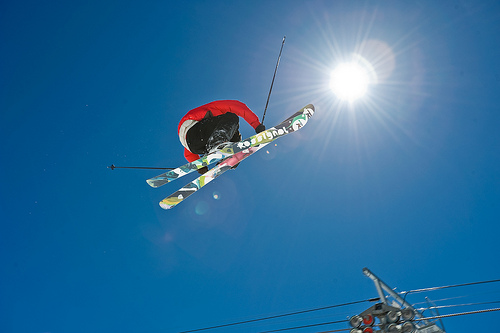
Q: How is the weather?
A: It is clear.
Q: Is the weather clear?
A: Yes, it is clear.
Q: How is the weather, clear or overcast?
A: It is clear.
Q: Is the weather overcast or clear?
A: It is clear.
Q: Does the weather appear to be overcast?
A: No, it is clear.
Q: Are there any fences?
A: No, there are no fences.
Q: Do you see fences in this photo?
A: No, there are no fences.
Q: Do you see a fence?
A: No, there are no fences.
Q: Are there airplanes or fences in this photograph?
A: No, there are no fences or airplanes.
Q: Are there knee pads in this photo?
A: No, there are no knee pads.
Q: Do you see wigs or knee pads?
A: No, there are no knee pads or wigs.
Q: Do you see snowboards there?
A: No, there are no snowboards.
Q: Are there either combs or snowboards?
A: No, there are no snowboards or combs.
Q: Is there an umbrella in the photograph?
A: No, there are no umbrellas.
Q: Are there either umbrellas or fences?
A: No, there are no umbrellas or fences.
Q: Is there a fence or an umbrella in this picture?
A: No, there are no umbrellas or fences.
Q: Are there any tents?
A: No, there are no tents.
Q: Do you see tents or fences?
A: No, there are no tents or fences.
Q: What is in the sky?
A: The sun is in the sky.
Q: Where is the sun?
A: The sun is in the sky.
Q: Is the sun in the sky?
A: Yes, the sun is in the sky.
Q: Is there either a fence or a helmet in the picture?
A: No, there are no helmets or fences.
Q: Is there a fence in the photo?
A: No, there are no fences.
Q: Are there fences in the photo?
A: No, there are no fences.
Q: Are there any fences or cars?
A: No, there are no fences or cars.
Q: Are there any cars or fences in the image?
A: No, there are no fences or cars.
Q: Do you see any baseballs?
A: No, there are no baseballs.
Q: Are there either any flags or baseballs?
A: No, there are no baseballs or flags.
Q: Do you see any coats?
A: Yes, there is a coat.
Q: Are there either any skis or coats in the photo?
A: Yes, there is a coat.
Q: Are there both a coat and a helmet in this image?
A: No, there is a coat but no helmets.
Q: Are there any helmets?
A: No, there are no helmets.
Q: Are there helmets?
A: No, there are no helmets.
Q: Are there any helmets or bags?
A: No, there are no helmets or bags.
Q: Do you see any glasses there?
A: No, there are no glasses.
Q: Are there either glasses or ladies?
A: No, there are no glasses or ladies.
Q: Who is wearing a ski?
A: The man is wearing a ski.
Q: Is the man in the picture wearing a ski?
A: Yes, the man is wearing a ski.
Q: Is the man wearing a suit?
A: No, the man is wearing a shoe.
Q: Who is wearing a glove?
A: The man is wearing a glove.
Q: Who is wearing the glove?
A: The man is wearing a glove.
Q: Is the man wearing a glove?
A: Yes, the man is wearing a glove.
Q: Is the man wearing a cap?
A: No, the man is wearing a glove.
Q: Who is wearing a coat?
A: The man is wearing a coat.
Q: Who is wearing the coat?
A: The man is wearing a coat.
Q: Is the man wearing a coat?
A: Yes, the man is wearing a coat.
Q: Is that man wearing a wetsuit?
A: No, the man is wearing a coat.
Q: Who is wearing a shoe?
A: The man is wearing a shoe.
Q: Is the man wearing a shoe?
A: Yes, the man is wearing a shoe.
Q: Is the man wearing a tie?
A: No, the man is wearing a shoe.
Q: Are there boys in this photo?
A: No, there are no boys.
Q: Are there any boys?
A: No, there are no boys.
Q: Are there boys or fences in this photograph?
A: No, there are no boys or fences.